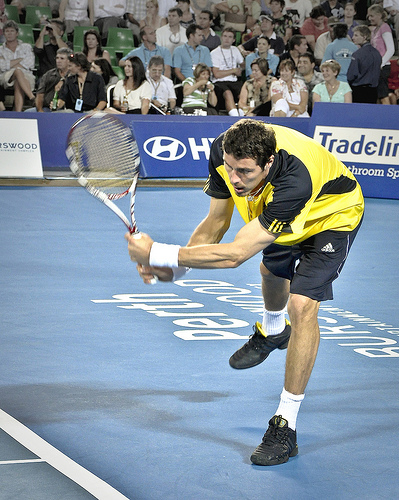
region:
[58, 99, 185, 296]
Tennis player swings his racket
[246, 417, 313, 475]
Man is wearing black tennis shoes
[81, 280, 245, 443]
The court is blue with white print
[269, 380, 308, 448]
The man is wearing a white sock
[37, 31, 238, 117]
The spectators look to the left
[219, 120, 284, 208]
The man has dark hair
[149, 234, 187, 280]
The man is wearing a white sweatband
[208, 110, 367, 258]
Man is wearing a yellow shirt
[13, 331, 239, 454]
Shadow on the tennis court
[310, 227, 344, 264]
Man wearing Adidas shorts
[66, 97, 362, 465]
a male tennis player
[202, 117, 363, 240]
a yellow and black jersey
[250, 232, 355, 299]
a pair of men's shorts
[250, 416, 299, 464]
a black tennis shoe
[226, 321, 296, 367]
a black tennis shoe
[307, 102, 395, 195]
a stadium promotional advertisement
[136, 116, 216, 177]
a stadium promotional advertisement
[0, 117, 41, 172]
a stadium promotional advertisement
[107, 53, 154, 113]
a woman in stands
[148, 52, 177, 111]
a man in stands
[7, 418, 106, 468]
white line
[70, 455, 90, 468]
white line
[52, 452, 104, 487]
white line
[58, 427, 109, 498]
white line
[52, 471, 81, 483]
white line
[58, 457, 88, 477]
white line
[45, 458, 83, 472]
white line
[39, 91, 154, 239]
a tennis racket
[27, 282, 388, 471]
a blue tennis court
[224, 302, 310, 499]
black athletic sneakers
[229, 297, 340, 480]
black athletic sneakers with white socks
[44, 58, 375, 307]
a man playing tennis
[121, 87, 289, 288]
a man wearing white arm bands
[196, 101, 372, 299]
a man wearing a yellow and black shirt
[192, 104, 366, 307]
a man wearing black shorts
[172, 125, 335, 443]
a man wearing white socks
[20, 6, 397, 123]
people watching a tennis game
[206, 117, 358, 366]
man's shirt is yellow and black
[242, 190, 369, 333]
man's shorts are black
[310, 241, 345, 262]
addidas sign on shorts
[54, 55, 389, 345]
men is leaning forwards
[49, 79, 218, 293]
man holding a racket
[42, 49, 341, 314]
man is playing tennis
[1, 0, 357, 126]
people watching the man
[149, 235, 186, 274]
man wearing a wristband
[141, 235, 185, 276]
the wristband is white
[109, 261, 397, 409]
white lettering on the court